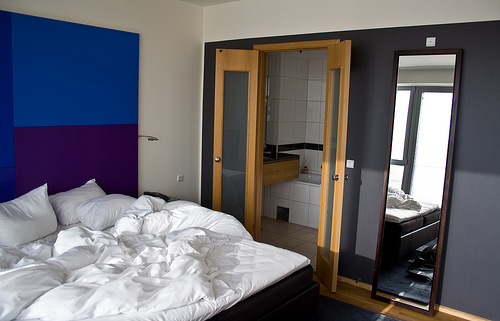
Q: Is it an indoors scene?
A: Yes, it is indoors.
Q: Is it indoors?
A: Yes, it is indoors.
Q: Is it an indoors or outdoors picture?
A: It is indoors.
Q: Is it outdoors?
A: No, it is indoors.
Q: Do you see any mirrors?
A: Yes, there is a mirror.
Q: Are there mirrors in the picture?
A: Yes, there is a mirror.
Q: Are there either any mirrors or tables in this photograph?
A: Yes, there is a mirror.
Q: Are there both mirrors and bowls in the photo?
A: No, there is a mirror but no bowls.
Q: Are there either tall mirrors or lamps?
A: Yes, there is a tall mirror.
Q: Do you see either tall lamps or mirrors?
A: Yes, there is a tall mirror.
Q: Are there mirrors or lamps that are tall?
A: Yes, the mirror is tall.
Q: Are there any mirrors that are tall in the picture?
A: Yes, there is a tall mirror.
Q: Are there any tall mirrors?
A: Yes, there is a tall mirror.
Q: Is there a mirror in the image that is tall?
A: Yes, there is a mirror that is tall.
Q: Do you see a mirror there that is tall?
A: Yes, there is a mirror that is tall.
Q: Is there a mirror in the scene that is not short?
A: Yes, there is a tall mirror.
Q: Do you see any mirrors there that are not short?
A: Yes, there is a tall mirror.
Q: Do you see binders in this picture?
A: No, there are no binders.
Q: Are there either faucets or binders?
A: No, there are no binders or faucets.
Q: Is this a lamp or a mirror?
A: This is a mirror.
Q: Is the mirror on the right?
A: Yes, the mirror is on the right of the image.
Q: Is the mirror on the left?
A: No, the mirror is on the right of the image.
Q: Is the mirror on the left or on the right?
A: The mirror is on the right of the image.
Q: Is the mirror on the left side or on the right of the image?
A: The mirror is on the right of the image.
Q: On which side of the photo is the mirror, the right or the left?
A: The mirror is on the right of the image.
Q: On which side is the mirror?
A: The mirror is on the right of the image.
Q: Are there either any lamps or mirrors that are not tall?
A: No, there is a mirror but it is tall.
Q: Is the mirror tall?
A: Yes, the mirror is tall.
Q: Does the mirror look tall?
A: Yes, the mirror is tall.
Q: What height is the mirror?
A: The mirror is tall.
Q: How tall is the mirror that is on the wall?
A: The mirror is tall.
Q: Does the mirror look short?
A: No, the mirror is tall.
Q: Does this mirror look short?
A: No, the mirror is tall.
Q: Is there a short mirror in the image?
A: No, there is a mirror but it is tall.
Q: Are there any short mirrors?
A: No, there is a mirror but it is tall.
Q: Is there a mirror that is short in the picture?
A: No, there is a mirror but it is tall.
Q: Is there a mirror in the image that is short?
A: No, there is a mirror but it is tall.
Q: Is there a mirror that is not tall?
A: No, there is a mirror but it is tall.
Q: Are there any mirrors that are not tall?
A: No, there is a mirror but it is tall.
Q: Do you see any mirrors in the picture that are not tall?
A: No, there is a mirror but it is tall.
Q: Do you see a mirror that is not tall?
A: No, there is a mirror but it is tall.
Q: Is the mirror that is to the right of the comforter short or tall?
A: The mirror is tall.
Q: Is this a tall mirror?
A: Yes, this is a tall mirror.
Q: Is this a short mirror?
A: No, this is a tall mirror.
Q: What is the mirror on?
A: The mirror is on the wall.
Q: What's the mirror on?
A: The mirror is on the wall.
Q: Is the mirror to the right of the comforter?
A: Yes, the mirror is to the right of the comforter.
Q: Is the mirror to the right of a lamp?
A: No, the mirror is to the right of the comforter.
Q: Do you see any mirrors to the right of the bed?
A: Yes, there is a mirror to the right of the bed.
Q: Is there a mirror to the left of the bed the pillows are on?
A: No, the mirror is to the right of the bed.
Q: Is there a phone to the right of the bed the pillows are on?
A: No, there is a mirror to the right of the bed.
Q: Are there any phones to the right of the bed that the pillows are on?
A: No, there is a mirror to the right of the bed.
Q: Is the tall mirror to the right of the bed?
A: Yes, the mirror is to the right of the bed.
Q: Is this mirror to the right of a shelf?
A: No, the mirror is to the right of the bed.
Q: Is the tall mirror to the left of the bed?
A: No, the mirror is to the right of the bed.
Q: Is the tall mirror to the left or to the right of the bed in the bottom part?
A: The mirror is to the right of the bed.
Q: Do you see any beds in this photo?
A: Yes, there is a bed.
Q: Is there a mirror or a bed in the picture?
A: Yes, there is a bed.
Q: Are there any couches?
A: No, there are no couches.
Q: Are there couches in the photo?
A: No, there are no couches.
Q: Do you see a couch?
A: No, there are no couches.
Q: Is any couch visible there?
A: No, there are no couches.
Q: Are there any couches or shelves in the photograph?
A: No, there are no couches or shelves.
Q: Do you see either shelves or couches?
A: No, there are no couches or shelves.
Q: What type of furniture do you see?
A: The furniture is a bed.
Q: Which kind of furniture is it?
A: The piece of furniture is a bed.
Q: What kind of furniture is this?
A: This is a bed.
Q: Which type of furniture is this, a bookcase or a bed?
A: This is a bed.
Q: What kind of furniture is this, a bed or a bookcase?
A: This is a bed.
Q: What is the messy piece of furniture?
A: The piece of furniture is a bed.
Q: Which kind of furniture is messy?
A: The furniture is a bed.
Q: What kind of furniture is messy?
A: The furniture is a bed.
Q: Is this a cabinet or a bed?
A: This is a bed.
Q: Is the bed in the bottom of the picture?
A: Yes, the bed is in the bottom of the image.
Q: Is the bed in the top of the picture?
A: No, the bed is in the bottom of the image.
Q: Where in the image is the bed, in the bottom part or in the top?
A: The bed is in the bottom of the image.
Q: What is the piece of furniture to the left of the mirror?
A: The piece of furniture is a bed.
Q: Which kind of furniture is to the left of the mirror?
A: The piece of furniture is a bed.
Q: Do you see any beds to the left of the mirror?
A: Yes, there is a bed to the left of the mirror.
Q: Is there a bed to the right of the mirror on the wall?
A: No, the bed is to the left of the mirror.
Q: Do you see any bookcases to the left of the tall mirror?
A: No, there is a bed to the left of the mirror.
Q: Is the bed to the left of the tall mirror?
A: Yes, the bed is to the left of the mirror.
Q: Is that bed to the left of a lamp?
A: No, the bed is to the left of the mirror.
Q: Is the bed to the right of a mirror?
A: No, the bed is to the left of a mirror.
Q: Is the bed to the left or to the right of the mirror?
A: The bed is to the left of the mirror.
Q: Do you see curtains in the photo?
A: No, there are no curtains.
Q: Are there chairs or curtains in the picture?
A: No, there are no curtains or chairs.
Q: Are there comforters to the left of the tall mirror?
A: Yes, there is a comforter to the left of the mirror.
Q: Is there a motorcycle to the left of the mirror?
A: No, there is a comforter to the left of the mirror.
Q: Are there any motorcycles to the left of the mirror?
A: No, there is a comforter to the left of the mirror.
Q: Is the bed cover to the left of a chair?
A: No, the bed cover is to the left of the mirror.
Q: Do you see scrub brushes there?
A: No, there are no scrub brushes.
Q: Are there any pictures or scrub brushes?
A: No, there are no scrub brushes or pictures.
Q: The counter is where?
A: The counter is in the bathroom.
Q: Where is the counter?
A: The counter is in the bathroom.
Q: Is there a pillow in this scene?
A: Yes, there is a pillow.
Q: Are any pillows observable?
A: Yes, there is a pillow.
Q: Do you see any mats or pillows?
A: Yes, there is a pillow.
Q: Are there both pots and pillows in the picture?
A: No, there is a pillow but no pots.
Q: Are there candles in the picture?
A: No, there are no candles.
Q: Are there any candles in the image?
A: No, there are no candles.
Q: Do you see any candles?
A: No, there are no candles.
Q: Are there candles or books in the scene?
A: No, there are no candles or books.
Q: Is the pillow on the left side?
A: Yes, the pillow is on the left of the image.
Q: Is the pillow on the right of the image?
A: No, the pillow is on the left of the image.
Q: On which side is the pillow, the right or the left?
A: The pillow is on the left of the image.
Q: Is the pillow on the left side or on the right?
A: The pillow is on the left of the image.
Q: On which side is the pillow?
A: The pillow is on the left of the image.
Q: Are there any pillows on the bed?
A: Yes, there is a pillow on the bed.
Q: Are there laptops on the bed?
A: No, there is a pillow on the bed.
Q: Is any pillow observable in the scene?
A: Yes, there are pillows.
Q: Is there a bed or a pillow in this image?
A: Yes, there are pillows.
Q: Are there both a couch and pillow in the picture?
A: No, there are pillows but no couches.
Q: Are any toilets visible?
A: No, there are no toilets.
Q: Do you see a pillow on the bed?
A: Yes, there are pillows on the bed.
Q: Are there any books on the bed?
A: No, there are pillows on the bed.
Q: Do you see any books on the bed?
A: No, there are pillows on the bed.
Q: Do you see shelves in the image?
A: No, there are no shelves.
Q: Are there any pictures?
A: No, there are no pictures.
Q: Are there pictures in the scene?
A: No, there are no pictures.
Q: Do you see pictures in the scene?
A: No, there are no pictures.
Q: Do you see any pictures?
A: No, there are no pictures.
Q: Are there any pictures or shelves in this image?
A: No, there are no pictures or shelves.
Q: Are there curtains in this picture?
A: No, there are no curtains.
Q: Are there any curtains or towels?
A: No, there are no curtains or towels.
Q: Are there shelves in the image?
A: No, there are no shelves.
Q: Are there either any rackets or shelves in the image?
A: No, there are no shelves or rackets.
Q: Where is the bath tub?
A: The bath tub is in the bathroom.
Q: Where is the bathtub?
A: The bath tub is in the bathroom.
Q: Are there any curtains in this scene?
A: No, there are no curtains.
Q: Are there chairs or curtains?
A: No, there are no curtains or chairs.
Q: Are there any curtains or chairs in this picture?
A: No, there are no curtains or chairs.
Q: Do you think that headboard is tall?
A: Yes, the headboard is tall.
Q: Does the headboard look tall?
A: Yes, the headboard is tall.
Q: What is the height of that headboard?
A: The headboard is tall.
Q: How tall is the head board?
A: The head board is tall.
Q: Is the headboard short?
A: No, the headboard is tall.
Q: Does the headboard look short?
A: No, the headboard is tall.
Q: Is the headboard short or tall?
A: The headboard is tall.